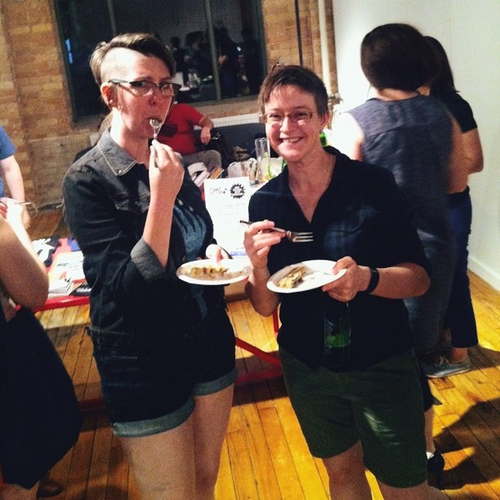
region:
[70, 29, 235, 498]
a woman is eating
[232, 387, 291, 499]
hardwood floor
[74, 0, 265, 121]
a big window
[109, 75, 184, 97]
woman is wearing eyeglasses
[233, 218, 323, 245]
a woman holding a fork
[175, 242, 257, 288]
a woman holding a plate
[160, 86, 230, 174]
a man sitting down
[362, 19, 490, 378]
two women standing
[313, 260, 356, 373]
a woman holding a beer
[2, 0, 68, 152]
a brick walll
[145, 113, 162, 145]
fork in lady's mouth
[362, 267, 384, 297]
wristwatch on lady's wrist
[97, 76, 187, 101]
glasses on lady's face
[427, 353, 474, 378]
shoes on lady's foot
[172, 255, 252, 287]
plate of food being held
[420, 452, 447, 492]
pump on lady's foot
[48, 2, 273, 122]
window in wall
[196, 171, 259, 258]
paper sign on table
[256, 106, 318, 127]
glasses on woman's face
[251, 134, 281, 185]
glass receptacle on table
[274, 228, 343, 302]
white plate with food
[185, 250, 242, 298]
white plate with food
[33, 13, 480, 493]
people at a party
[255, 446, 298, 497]
light colored wood floor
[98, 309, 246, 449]
blue jean shorts on woman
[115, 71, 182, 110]
glasses on woman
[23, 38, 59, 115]
brick back wall with window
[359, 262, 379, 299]
black wristband on arm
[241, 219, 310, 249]
silver fork in right hand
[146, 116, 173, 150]
eating utensil in mouth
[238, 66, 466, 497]
the woman is smiling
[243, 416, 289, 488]
the floor is wooden and brown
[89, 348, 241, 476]
the shorts are short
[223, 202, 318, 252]
the fork is metal and silver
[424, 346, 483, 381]
the shoe is blue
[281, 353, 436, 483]
the shorts are green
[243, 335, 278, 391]
the table legs are red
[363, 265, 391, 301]
the watch is black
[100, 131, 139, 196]
the shirt has a collar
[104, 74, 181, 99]
the woman wears glasses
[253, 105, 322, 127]
the woman wears glasses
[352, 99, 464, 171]
the shirt is sleeveless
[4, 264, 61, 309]
the elbow is bent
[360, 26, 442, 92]
her hair is short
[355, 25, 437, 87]
her hair is brown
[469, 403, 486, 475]
a shadow on the floor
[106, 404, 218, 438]
shorts are cuffed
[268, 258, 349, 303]
food is on the plate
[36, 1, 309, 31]
the window is big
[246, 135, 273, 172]
the glass is tall